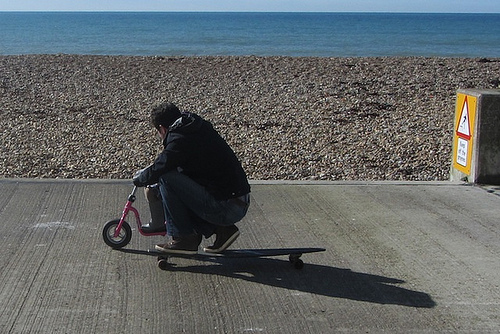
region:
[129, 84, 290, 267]
the guy is on the skateboard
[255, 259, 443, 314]
shadow is on the ground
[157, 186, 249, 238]
the jeans are green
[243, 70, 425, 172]
the beach has pebbles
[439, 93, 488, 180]
the sign is yellow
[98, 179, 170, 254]
the scooter is pink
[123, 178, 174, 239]
the child is on the mowped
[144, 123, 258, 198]
the jaccket is black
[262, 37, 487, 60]
water is on the horizon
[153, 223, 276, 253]
the shoes are brown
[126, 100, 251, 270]
adult crouched on front of skateboard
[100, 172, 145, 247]
black tire on small pink scooter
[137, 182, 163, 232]
leg on platform of scooter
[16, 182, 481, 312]
ridged surface of concrete path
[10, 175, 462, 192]
smooth edging on path border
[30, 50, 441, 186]
grey pebbled surface between path and ocean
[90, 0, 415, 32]
light blue sky over darker blue ocean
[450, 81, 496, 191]
oblong container leaning against path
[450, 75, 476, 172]
red, white and black sign on yellow background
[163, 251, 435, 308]
shadow of figures on wheels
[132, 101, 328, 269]
a man kneeling on a skateboard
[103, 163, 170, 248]
a child on a scooter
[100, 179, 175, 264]
a child on the scooter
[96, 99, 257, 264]
the man is bending over and helping the child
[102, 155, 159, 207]
the man is holding the scooter handlebars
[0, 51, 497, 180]
pebbles on the beach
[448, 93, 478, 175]
a warning sign on the boardwalk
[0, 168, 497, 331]
the boardwalk is concrete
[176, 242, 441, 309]
a shadow on the concrete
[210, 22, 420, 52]
the water is still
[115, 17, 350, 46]
the water is calm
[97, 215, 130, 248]
the tire is small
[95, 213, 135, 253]
the tire is black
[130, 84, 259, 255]
the man is kneeling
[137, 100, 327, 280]
the man is on the skateboard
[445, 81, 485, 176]
the sign is red yellow and white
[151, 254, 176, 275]
the wheel is black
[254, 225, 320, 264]
the skateboard is black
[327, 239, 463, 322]
the shadow is on the ground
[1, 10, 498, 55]
a large body of water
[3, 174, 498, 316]
the cement walk way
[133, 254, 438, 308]
the shadow on the ground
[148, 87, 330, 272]
the man on a skateboard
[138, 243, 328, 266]
the skateboard on the ground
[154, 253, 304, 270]
the wheels on the skateboard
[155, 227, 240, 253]
the shoes on the man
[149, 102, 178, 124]
the hair on the man's head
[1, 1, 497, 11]
a part of the clear blue sky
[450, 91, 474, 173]
the yellow sign